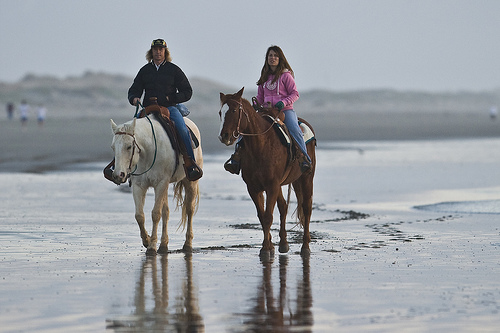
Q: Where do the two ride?
A: Along a beach.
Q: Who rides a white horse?
A: The male rider.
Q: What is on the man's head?
A: A cap.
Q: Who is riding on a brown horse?
A: A woman.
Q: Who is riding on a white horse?
A: A man.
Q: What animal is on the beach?
A: Horse.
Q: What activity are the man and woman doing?
A: Riding horses.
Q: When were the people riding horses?
A: During daylight hours.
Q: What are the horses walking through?
A: Water.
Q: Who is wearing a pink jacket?
A: A woman.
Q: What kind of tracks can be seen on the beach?
A: Horse tracks.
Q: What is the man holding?
A: Reins.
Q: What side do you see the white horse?
A: Left side.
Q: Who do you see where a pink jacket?
A: The female rider.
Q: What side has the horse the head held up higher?
A: The brown horse on the right.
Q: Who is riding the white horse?
A: The male.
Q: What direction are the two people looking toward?
A: Toward the camera.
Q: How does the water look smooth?
A: A wave was on the beach.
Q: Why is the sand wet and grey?
A: It is currently at low tide.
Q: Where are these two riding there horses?
A: On the beach.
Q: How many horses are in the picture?
A: 2.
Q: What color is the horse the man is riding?
A: White.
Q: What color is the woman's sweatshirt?
A: Pink.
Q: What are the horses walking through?
A: Water.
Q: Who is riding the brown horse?
A: The woman.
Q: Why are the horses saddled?
A: For riding.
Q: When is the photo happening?
A: Daytime.